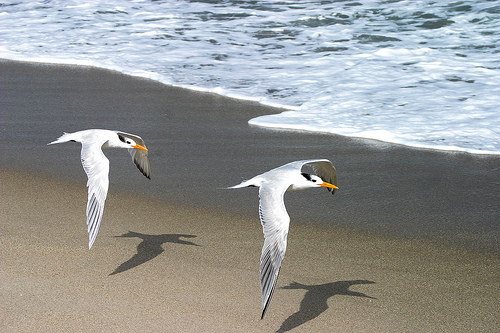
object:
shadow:
[108, 229, 203, 276]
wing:
[277, 157, 338, 194]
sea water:
[0, 0, 499, 155]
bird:
[213, 158, 339, 319]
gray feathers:
[257, 243, 287, 320]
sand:
[0, 58, 499, 332]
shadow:
[273, 278, 378, 333]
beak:
[319, 181, 339, 190]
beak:
[132, 143, 149, 151]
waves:
[0, 0, 499, 155]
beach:
[0, 0, 499, 331]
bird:
[45, 129, 151, 251]